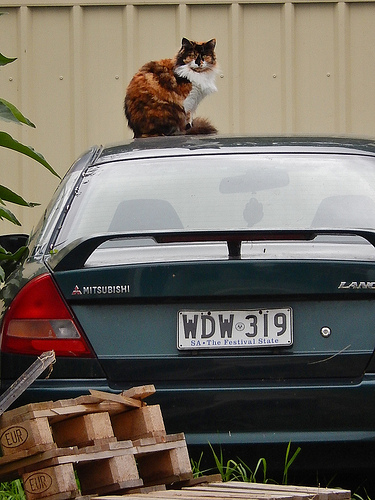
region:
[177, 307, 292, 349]
License plate on green car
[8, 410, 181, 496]
Blocks of brown wood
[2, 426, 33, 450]
EUR logo on wood blocks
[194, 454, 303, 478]
Blades of green grass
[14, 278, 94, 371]
Green car left tail light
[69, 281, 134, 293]
Car brand logo badge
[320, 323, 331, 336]
Car trunk key hole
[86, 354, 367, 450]
Green car back bumper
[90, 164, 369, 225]
Green car back windshield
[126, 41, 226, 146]
White and brown cat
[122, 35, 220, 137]
a seated fluffy cat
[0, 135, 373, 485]
the back of a green sedan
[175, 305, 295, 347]
a white and black license plate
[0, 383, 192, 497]
the edge of two wooden pallets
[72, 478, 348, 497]
the top slats of a wooden pallet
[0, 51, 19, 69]
the tip of a green leaf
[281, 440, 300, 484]
two blades of grass standing upright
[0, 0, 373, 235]
a cream colored painted metal wall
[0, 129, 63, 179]
a broad green leaf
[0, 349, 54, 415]
a length of metal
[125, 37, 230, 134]
the cat is sitting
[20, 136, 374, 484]
the cat is on top of the car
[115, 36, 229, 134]
the cat is black orange and white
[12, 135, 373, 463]
the car has a license plate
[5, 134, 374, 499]
the car is blue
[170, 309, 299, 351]
the license plate has lettering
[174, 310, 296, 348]
the license plate is white black and blue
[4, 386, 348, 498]
the wood is beside the car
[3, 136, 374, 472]
the car has seats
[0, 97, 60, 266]
the leaves are green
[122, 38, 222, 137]
Calico cat in sitting position.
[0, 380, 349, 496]
Three wooden pallets are piled up.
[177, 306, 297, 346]
License plate from the festival state.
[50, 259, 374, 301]
Edge of trunk deck on Mitsubishi Lancer.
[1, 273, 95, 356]
Three lens colors in a taillight.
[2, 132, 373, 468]
Rear view of a green car.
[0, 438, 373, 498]
Green grass blades behind wooden pallets.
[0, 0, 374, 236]
Tan wall behind cat has ribs vertical.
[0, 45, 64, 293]
Green leaves partly obscure tan wall.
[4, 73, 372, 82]
Row of fasteners behind fuzzy fur.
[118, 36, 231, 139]
very fluffy and colorful cat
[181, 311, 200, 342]
the letter "W" on the license plate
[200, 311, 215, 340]
the letter "D" on the license plate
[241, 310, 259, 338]
the number 3 on the license plate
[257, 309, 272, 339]
the number 1 on the license plate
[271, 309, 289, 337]
the number 9 on the license plate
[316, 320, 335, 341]
keyhole on the trunk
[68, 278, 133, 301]
the Mitsubishi logo on the car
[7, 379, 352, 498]
wooden pallets behind the car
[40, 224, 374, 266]
spoiler on rear of the car